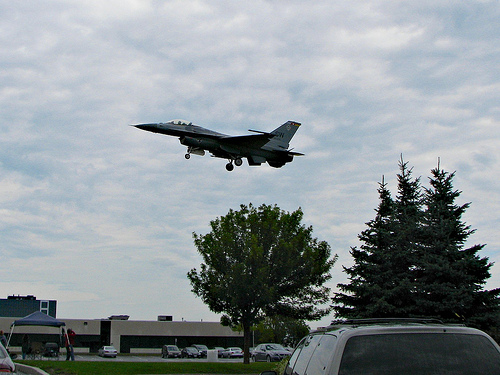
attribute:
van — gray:
[294, 310, 442, 372]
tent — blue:
[20, 280, 97, 362]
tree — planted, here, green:
[182, 188, 317, 352]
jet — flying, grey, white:
[119, 99, 310, 181]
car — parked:
[93, 346, 126, 370]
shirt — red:
[66, 337, 76, 347]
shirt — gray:
[24, 347, 41, 357]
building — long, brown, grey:
[28, 288, 283, 363]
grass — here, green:
[82, 356, 210, 375]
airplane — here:
[135, 104, 328, 167]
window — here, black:
[333, 301, 497, 374]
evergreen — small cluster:
[411, 153, 500, 323]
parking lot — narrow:
[15, 325, 320, 373]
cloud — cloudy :
[211, 15, 312, 80]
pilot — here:
[170, 116, 206, 149]